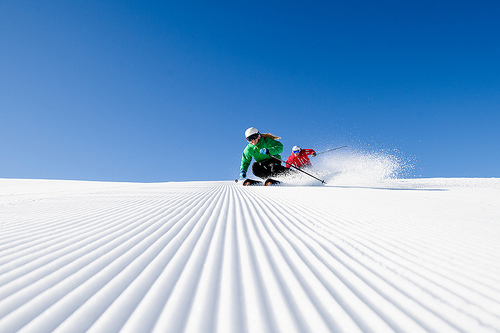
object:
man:
[283, 145, 316, 170]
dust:
[326, 144, 416, 186]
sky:
[0, 0, 499, 184]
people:
[237, 125, 290, 179]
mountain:
[0, 177, 499, 332]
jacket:
[283, 148, 315, 170]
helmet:
[290, 144, 300, 153]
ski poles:
[314, 144, 347, 156]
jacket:
[229, 133, 284, 175]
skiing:
[233, 125, 329, 186]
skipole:
[233, 176, 241, 182]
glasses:
[244, 130, 259, 142]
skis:
[262, 177, 282, 186]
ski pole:
[266, 153, 327, 185]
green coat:
[238, 135, 283, 174]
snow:
[0, 177, 499, 333]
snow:
[281, 135, 419, 186]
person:
[283, 145, 316, 171]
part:
[243, 1, 320, 130]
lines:
[116, 183, 225, 332]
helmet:
[243, 126, 258, 138]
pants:
[250, 157, 289, 180]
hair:
[258, 133, 280, 142]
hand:
[258, 146, 268, 156]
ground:
[0, 177, 499, 332]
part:
[319, 0, 499, 179]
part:
[0, 0, 239, 184]